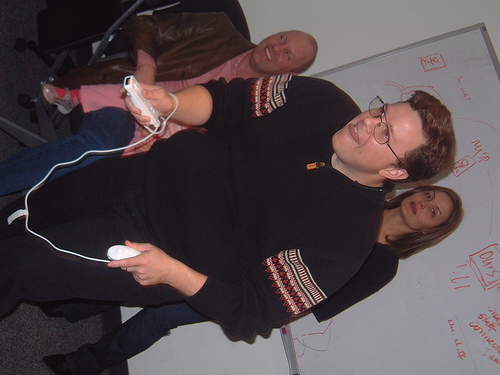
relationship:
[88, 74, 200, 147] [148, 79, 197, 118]
controller in hand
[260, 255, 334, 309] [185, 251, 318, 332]
design on sleeve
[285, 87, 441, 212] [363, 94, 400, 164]
man has glasses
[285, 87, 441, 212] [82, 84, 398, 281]
man in foreground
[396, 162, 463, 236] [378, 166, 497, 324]
woman in background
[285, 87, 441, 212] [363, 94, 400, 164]
man with glasses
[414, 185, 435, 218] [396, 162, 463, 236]
eyes of woman